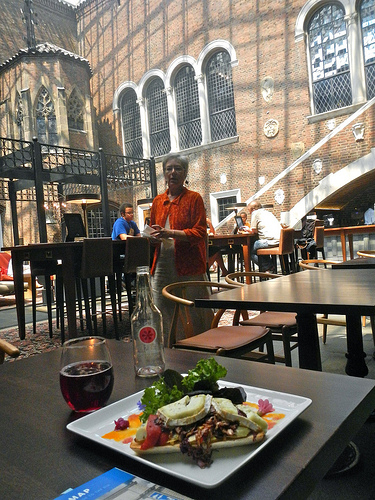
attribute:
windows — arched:
[104, 41, 253, 161]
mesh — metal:
[210, 71, 230, 109]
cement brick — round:
[254, 116, 288, 141]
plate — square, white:
[62, 368, 315, 490]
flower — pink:
[248, 390, 286, 427]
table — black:
[224, 225, 362, 328]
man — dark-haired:
[102, 203, 166, 241]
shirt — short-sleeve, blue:
[106, 213, 139, 238]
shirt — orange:
[144, 185, 210, 267]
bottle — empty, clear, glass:
[128, 260, 184, 388]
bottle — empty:
[129, 270, 166, 379]